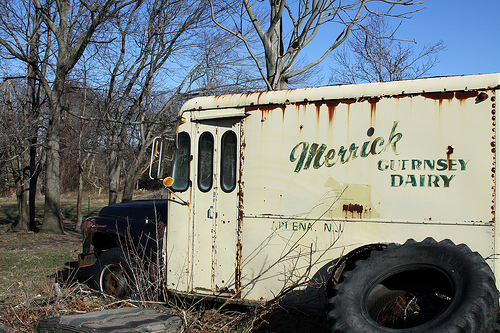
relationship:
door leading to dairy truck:
[191, 117, 243, 294] [61, 72, 500, 330]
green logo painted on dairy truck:
[287, 121, 469, 189] [61, 72, 500, 330]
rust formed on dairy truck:
[241, 87, 491, 114] [61, 72, 500, 330]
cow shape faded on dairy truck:
[322, 176, 381, 220] [61, 72, 500, 330]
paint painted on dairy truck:
[84, 195, 171, 287] [61, 72, 500, 330]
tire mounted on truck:
[89, 250, 145, 306] [130, 128, 280, 252]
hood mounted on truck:
[96, 195, 167, 225] [46, 49, 494, 317]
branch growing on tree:
[0, 16, 25, 54] [2, 2, 84, 231]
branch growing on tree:
[0, 0, 445, 333] [2, 2, 84, 231]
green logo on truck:
[284, 119, 474, 197] [146, 72, 498, 310]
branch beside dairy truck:
[0, 0, 445, 333] [61, 72, 500, 330]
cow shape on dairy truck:
[325, 179, 374, 216] [61, 72, 500, 330]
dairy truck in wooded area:
[61, 72, 500, 330] [1, 1, 171, 241]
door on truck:
[191, 117, 243, 294] [146, 72, 498, 310]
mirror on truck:
[146, 133, 163, 187] [146, 72, 498, 310]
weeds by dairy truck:
[0, 184, 348, 331] [61, 72, 500, 330]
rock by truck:
[33, 304, 188, 331] [146, 72, 498, 310]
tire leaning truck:
[307, 207, 474, 331] [325, 219, 497, 330]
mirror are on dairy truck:
[150, 135, 168, 180] [61, 72, 500, 330]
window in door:
[217, 123, 242, 191] [192, 117, 242, 299]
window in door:
[199, 132, 213, 194] [192, 117, 242, 299]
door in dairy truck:
[192, 117, 242, 299] [61, 72, 500, 330]